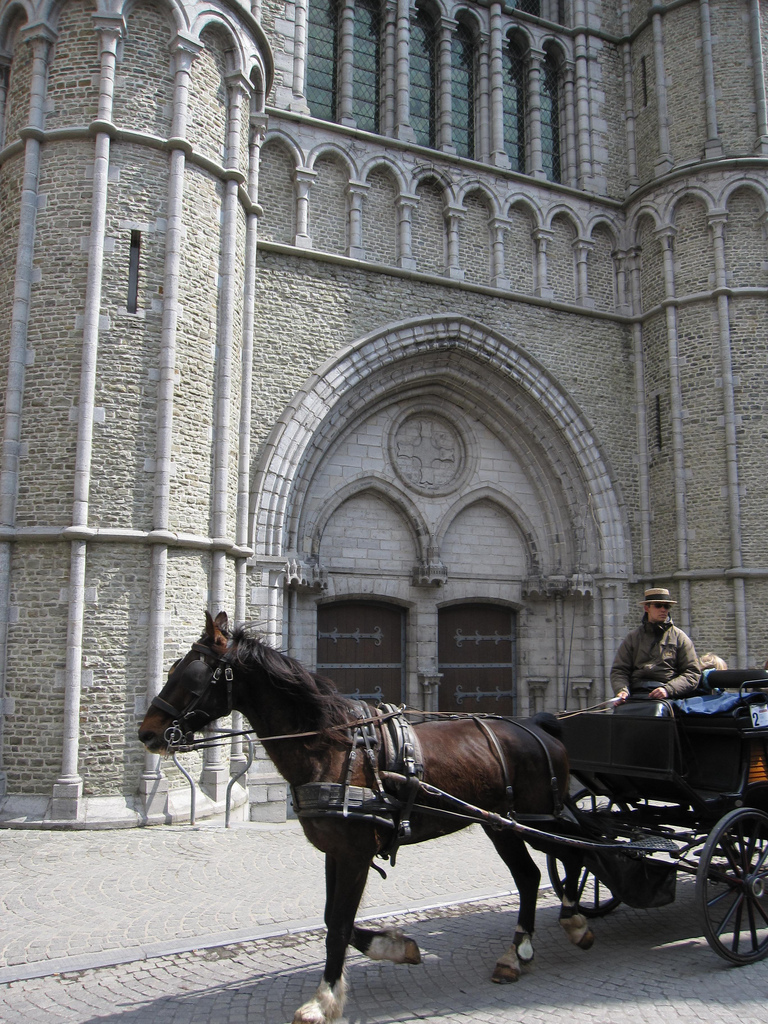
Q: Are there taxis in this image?
A: No, there are no taxis.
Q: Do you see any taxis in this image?
A: No, there are no taxis.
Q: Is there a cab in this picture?
A: No, there are no taxis.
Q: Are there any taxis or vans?
A: No, there are no taxis or vans.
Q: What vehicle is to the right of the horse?
A: The vehicle is a carriage.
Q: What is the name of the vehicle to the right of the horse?
A: The vehicle is a carriage.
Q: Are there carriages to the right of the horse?
A: Yes, there is a carriage to the right of the horse.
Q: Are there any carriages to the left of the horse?
A: No, the carriage is to the right of the horse.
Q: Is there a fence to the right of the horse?
A: No, there is a carriage to the right of the horse.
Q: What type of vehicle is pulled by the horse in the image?
A: The vehicle is a carriage.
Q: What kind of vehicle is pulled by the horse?
A: The vehicle is a carriage.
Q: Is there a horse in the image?
A: Yes, there is a horse.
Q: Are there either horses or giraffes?
A: Yes, there is a horse.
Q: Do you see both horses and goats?
A: No, there is a horse but no goats.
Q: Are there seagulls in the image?
A: No, there are no seagulls.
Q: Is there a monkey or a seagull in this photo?
A: No, there are no seagulls or monkeys.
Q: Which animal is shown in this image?
A: The animal is a horse.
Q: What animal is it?
A: The animal is a horse.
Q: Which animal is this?
A: This is a horse.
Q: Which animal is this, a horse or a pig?
A: This is a horse.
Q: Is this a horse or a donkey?
A: This is a horse.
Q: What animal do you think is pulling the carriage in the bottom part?
A: The horse is pulling the carriage.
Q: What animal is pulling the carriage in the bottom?
A: The animal is a horse.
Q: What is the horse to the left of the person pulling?
A: The horse is pulling the carriage.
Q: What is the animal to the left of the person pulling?
A: The horse is pulling the carriage.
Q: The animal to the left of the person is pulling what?
A: The horse is pulling the carriage.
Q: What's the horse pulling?
A: The horse is pulling the carriage.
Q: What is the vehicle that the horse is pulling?
A: The vehicle is a carriage.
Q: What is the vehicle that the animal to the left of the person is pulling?
A: The vehicle is a carriage.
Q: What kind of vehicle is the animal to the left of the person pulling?
A: The horse is pulling the carriage.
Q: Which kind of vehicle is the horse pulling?
A: The horse is pulling the carriage.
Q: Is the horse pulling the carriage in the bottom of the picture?
A: Yes, the horse is pulling the carriage.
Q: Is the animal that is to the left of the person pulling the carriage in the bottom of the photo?
A: Yes, the horse is pulling the carriage.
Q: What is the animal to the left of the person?
A: The animal is a horse.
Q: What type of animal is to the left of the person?
A: The animal is a horse.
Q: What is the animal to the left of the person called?
A: The animal is a horse.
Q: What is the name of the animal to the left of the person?
A: The animal is a horse.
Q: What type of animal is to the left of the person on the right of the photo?
A: The animal is a horse.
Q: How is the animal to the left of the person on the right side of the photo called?
A: The animal is a horse.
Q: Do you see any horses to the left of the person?
A: Yes, there is a horse to the left of the person.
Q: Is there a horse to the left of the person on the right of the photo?
A: Yes, there is a horse to the left of the person.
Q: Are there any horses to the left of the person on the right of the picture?
A: Yes, there is a horse to the left of the person.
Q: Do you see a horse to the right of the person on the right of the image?
A: No, the horse is to the left of the person.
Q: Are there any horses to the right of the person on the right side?
A: No, the horse is to the left of the person.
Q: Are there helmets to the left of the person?
A: No, there is a horse to the left of the person.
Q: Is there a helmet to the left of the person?
A: No, there is a horse to the left of the person.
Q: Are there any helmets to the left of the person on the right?
A: No, there is a horse to the left of the person.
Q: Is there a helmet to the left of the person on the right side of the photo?
A: No, there is a horse to the left of the person.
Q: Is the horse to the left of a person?
A: Yes, the horse is to the left of a person.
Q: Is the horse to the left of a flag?
A: No, the horse is to the left of a person.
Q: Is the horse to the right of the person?
A: No, the horse is to the left of the person.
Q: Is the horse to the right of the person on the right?
A: No, the horse is to the left of the person.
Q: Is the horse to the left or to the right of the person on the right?
A: The horse is to the left of the person.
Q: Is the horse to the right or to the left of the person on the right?
A: The horse is to the left of the person.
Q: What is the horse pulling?
A: The horse is pulling the carriage.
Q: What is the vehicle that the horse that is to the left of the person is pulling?
A: The vehicle is a carriage.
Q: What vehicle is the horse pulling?
A: The horse is pulling the carriage.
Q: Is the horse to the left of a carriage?
A: Yes, the horse is to the left of a carriage.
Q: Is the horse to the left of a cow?
A: No, the horse is to the left of a carriage.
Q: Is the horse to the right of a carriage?
A: No, the horse is to the left of a carriage.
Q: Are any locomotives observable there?
A: No, there are no locomotives.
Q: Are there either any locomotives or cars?
A: No, there are no locomotives or cars.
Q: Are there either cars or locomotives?
A: No, there are no locomotives or cars.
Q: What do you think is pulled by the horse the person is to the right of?
A: The carriage is pulled by the horse.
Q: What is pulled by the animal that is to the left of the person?
A: The carriage is pulled by the horse.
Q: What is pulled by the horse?
A: The carriage is pulled by the horse.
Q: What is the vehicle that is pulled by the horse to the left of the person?
A: The vehicle is a carriage.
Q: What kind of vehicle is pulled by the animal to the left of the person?
A: The vehicle is a carriage.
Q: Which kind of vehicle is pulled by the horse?
A: The vehicle is a carriage.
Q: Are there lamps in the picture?
A: No, there are no lamps.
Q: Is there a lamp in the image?
A: No, there are no lamps.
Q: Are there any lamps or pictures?
A: No, there are no lamps or pictures.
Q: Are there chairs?
A: No, there are no chairs.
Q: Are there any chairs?
A: No, there are no chairs.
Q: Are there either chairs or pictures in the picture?
A: No, there are no chairs or pictures.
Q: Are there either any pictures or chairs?
A: No, there are no chairs or pictures.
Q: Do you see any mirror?
A: No, there are no mirrors.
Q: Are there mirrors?
A: No, there are no mirrors.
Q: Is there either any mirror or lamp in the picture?
A: No, there are no mirrors or lamps.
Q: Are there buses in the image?
A: No, there are no buses.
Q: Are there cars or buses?
A: No, there are no buses or cars.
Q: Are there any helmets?
A: No, there are no helmets.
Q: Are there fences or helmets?
A: No, there are no helmets or fences.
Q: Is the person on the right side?
A: Yes, the person is on the right of the image.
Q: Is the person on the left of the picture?
A: No, the person is on the right of the image.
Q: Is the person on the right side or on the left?
A: The person is on the right of the image.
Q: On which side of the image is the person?
A: The person is on the right of the image.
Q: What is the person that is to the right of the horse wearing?
A: The person is wearing a jacket.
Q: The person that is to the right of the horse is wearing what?
A: The person is wearing a jacket.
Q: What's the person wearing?
A: The person is wearing a jacket.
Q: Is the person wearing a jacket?
A: Yes, the person is wearing a jacket.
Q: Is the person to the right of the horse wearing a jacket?
A: Yes, the person is wearing a jacket.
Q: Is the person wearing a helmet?
A: No, the person is wearing a jacket.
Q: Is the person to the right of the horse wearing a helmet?
A: No, the person is wearing a jacket.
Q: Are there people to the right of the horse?
A: Yes, there is a person to the right of the horse.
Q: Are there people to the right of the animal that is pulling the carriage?
A: Yes, there is a person to the right of the horse.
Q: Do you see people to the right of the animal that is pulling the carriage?
A: Yes, there is a person to the right of the horse.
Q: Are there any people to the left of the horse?
A: No, the person is to the right of the horse.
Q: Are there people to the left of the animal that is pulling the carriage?
A: No, the person is to the right of the horse.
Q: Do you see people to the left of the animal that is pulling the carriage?
A: No, the person is to the right of the horse.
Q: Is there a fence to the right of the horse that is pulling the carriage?
A: No, there is a person to the right of the horse.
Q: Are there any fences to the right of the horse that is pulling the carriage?
A: No, there is a person to the right of the horse.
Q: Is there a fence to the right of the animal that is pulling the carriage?
A: No, there is a person to the right of the horse.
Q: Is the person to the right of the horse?
A: Yes, the person is to the right of the horse.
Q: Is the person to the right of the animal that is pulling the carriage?
A: Yes, the person is to the right of the horse.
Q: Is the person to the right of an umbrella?
A: No, the person is to the right of the horse.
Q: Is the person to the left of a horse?
A: No, the person is to the right of a horse.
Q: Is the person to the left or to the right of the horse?
A: The person is to the right of the horse.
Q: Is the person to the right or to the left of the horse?
A: The person is to the right of the horse.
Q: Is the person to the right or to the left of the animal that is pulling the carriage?
A: The person is to the right of the horse.